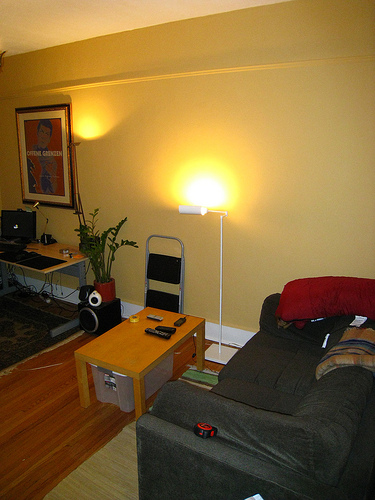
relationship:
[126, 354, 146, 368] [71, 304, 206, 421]
part of a table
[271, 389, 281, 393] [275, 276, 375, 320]
part of a blanket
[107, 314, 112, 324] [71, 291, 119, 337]
part of a speaker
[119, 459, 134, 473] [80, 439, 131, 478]
part of a floor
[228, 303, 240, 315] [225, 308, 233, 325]
part of a wall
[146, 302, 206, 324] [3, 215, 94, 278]
edge of a table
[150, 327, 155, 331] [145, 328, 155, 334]
part of a remote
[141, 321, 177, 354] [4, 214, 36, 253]
remote of tv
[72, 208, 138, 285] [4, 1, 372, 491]
plant in room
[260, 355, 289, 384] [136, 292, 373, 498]
part of black couch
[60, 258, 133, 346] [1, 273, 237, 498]
speaker on ground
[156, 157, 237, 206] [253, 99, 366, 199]
light shining on wall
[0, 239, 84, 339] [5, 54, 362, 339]
desk against wall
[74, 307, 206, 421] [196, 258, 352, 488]
coffee table in front of couch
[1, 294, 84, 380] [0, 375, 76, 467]
carpet on floor